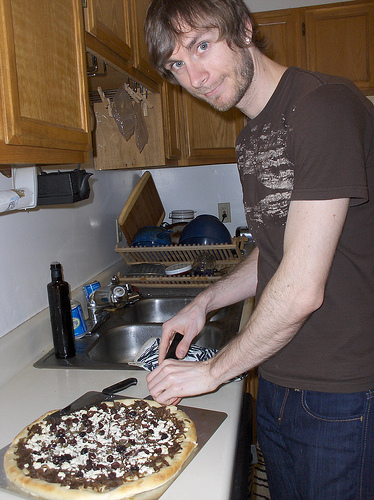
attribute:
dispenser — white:
[2, 166, 40, 216]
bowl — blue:
[177, 214, 232, 249]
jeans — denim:
[256, 381, 372, 500]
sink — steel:
[90, 287, 154, 368]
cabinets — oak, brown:
[2, 1, 162, 167]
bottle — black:
[46, 259, 81, 358]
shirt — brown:
[234, 90, 374, 370]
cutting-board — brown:
[112, 168, 167, 245]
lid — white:
[165, 261, 190, 276]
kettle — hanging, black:
[37, 166, 96, 211]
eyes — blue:
[167, 59, 188, 72]